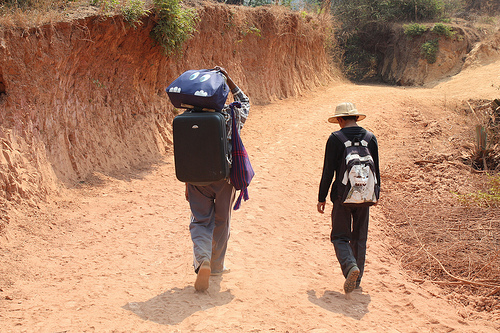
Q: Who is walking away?
A: Man with hat.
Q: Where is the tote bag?
A: On his head.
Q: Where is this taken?
A: On a dirt road.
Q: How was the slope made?
A: Man made.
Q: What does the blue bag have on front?
A: Face.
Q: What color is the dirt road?
A: Red.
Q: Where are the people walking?
A: Dirt road.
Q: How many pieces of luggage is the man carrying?
A: 2.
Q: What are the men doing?
A: Walking away.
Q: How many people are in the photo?
A: Two.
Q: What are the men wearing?
A: Backpacks.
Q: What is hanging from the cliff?
A: Bush.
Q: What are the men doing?
A: Walking.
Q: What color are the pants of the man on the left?
A: Grey.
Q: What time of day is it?
A: Daytime.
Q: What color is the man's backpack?
A: Black and white.